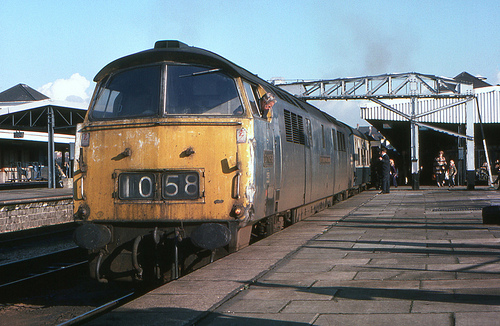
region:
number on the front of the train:
[117, 171, 194, 201]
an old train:
[78, 50, 368, 226]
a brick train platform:
[160, 184, 481, 315]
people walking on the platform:
[427, 150, 457, 185]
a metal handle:
[230, 170, 244, 196]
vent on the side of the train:
[280, 109, 303, 144]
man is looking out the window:
[255, 90, 274, 117]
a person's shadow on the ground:
[247, 277, 497, 307]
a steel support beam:
[45, 110, 56, 187]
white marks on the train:
[137, 130, 160, 149]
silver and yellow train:
[84, 68, 385, 243]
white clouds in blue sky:
[358, 22, 395, 56]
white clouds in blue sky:
[305, 19, 332, 49]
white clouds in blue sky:
[237, 8, 278, 38]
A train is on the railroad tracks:
[18, 22, 473, 287]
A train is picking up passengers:
[46, 16, 481, 294]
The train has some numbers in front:
[38, 20, 463, 300]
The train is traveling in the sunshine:
[26, 6, 481, 301]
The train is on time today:
[11, 35, 406, 321]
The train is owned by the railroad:
[33, 18, 470, 304]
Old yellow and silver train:
[67, 39, 373, 282]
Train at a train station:
[67, 39, 381, 277]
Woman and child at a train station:
[431, 145, 458, 187]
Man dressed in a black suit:
[372, 142, 391, 197]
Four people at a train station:
[372, 140, 460, 198]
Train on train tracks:
[70, 39, 382, 286]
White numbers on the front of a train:
[113, 168, 204, 206]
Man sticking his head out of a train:
[230, 86, 276, 119]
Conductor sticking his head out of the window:
[231, 90, 277, 122]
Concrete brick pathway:
[174, 184, 499, 324]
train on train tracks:
[67, 33, 387, 295]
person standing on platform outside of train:
[368, 143, 403, 197]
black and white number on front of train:
[103, 160, 214, 210]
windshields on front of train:
[82, 58, 251, 128]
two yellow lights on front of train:
[69, 197, 246, 224]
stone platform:
[107, 186, 493, 323]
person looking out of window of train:
[245, 81, 282, 138]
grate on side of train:
[277, 103, 317, 161]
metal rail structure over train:
[277, 68, 489, 196]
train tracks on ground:
[1, 254, 121, 324]